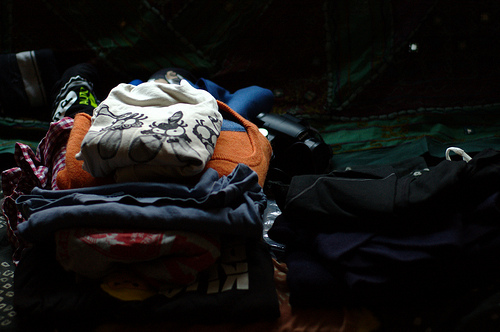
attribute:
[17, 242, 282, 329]
shirt — black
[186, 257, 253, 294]
writing — white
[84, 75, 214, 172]
shirt — red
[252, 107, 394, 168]
camera — black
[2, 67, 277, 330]
clothes — piled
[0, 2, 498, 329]
room — dark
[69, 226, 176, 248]
shirt — red and white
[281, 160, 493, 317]
shirt — dark, black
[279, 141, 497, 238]
shirt — black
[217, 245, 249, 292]
letter — white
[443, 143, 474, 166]
string — white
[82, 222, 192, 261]
design — red and grey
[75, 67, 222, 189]
t-shirt — silly, white and black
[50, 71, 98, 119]
green shirt — crumpled, black and white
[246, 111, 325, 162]
bottle — black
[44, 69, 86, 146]
design — green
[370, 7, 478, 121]
bag — black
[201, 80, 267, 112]
cloth — blue